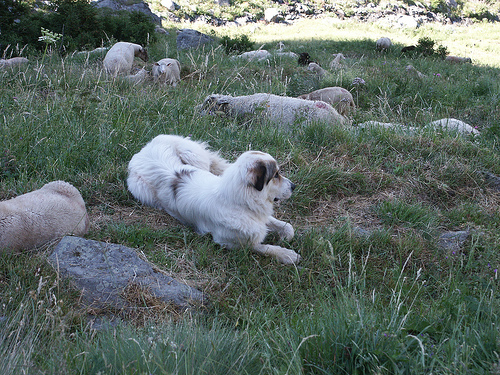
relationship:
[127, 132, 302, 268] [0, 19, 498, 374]
dog laying in grass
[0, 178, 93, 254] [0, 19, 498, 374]
sheep laying in grass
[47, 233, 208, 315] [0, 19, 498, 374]
rock in grass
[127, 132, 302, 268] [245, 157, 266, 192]
dog has ears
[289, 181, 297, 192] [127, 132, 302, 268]
nose apart of dog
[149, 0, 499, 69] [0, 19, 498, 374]
ray of sun on grass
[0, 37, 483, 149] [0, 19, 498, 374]
group of sheep laying in grass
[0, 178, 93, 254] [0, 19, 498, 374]
sheep resting in grass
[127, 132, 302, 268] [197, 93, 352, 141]
dog relaxing by sheep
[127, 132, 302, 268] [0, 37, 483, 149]
dog watching group of sheep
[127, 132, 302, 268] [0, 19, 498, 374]
dog on grass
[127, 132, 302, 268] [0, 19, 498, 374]
dog in grass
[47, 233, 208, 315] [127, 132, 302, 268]
rock near dog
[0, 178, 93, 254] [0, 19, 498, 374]
sheep in grass